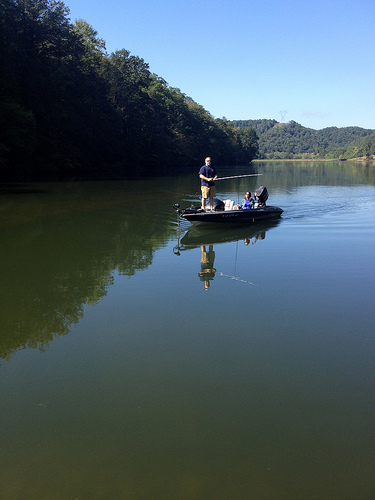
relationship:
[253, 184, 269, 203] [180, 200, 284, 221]
trolling motor on boat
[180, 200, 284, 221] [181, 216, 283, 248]
boat has reflection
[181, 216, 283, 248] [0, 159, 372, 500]
reflection in water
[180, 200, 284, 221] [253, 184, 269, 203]
boat has trolling motor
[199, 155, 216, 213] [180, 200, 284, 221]
man on boat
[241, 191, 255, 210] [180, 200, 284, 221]
woman sitting in boat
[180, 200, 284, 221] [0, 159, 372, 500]
boat in water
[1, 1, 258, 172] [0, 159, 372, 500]
trees are along water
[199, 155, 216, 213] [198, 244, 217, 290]
man has reflection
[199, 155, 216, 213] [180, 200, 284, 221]
man in boat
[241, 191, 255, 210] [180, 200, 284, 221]
woman in boat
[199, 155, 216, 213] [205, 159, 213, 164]
man wearing sunglasses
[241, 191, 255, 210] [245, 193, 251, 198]
woman wearing sunglasses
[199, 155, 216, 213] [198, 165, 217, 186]
man wearing shirt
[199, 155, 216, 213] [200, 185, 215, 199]
man wearing shorts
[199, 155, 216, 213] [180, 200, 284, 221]
man riding in boat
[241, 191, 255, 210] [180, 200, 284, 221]
woman riding in boat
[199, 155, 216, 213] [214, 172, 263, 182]
man holding fishing pole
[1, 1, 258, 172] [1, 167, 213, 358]
trees have reflection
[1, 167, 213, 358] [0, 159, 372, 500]
reflection in water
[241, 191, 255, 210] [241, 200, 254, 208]
woman wearing shirt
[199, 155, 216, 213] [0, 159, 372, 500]
man in water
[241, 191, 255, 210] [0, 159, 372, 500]
woman in water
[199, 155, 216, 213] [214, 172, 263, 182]
man using fishing pole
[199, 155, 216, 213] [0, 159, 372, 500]
man enjoying water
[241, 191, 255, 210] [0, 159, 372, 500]
woman enjoying water